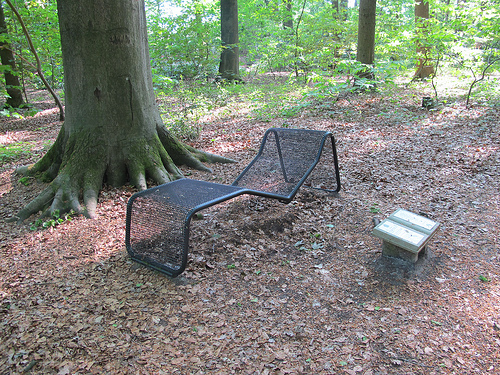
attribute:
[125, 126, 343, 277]
bench — black, bent, metal, wide, curved, empty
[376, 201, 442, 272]
statue — cement, small, brown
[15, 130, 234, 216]
tree roots — exposed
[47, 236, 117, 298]
leaves — dead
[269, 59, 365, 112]
vegetation — green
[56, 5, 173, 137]
tree trunk — brown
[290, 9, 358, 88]
tree — small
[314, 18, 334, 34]
leaves — green